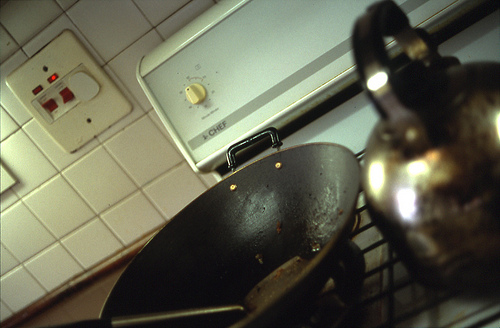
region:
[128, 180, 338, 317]
the pan is black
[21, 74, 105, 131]
the light is on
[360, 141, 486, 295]
the kettle is silver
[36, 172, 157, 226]
the tiles are white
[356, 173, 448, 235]
light reflection is on the kettle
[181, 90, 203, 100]
the knob is yellow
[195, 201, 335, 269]
the pan has leftovers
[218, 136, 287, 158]
the handle is black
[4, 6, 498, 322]
the scene is in the kitchen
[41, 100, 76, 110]
the switch is red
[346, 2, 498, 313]
tarnished silver tea kettle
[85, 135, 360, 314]
dirty fry pan on stove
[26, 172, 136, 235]
white tiles on backsplash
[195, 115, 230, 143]
brand name on oven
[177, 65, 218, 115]
temperature control for oven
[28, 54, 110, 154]
electrical switches for appliance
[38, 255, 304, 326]
stainless steel spatula in fry pan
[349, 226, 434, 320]
black burner grates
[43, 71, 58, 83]
tiny red shining light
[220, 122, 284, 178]
black handle on fry pan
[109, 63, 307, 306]
the pan is black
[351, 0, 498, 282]
Black and silver kettle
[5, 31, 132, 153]
Set of buttons to control power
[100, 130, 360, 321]
Round black pan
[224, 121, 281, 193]
Handle of the pan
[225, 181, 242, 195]
Screw used to connect a handle to the pan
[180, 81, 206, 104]
Switch to regulate temperature levels on the stove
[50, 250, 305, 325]
Spoon used to mix food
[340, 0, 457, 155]
Handle of kettle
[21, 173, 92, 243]
White tile on the wall of the kitchen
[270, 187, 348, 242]
Group of crumbles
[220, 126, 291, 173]
shiny black wok handle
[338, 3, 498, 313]
shiny metal teakettle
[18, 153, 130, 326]
square white tiles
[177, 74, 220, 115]
small white stove knob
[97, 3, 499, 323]
pan and kettle on stove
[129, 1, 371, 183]
white back panel of stove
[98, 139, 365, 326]
empty black pan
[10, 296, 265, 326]
metal utensil with black handle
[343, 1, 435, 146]
shiny curved tea kettle handle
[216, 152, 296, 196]
two handle screws on pot